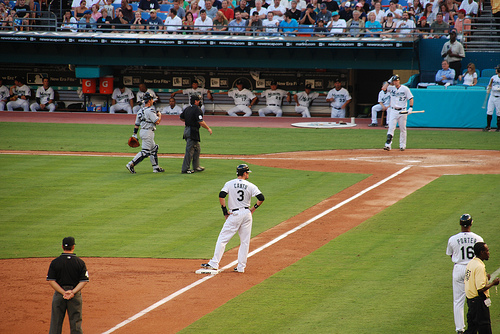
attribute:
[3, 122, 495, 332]
grass — short, green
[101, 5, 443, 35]
people — Watching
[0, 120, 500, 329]
ground — Brown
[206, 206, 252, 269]
trouser — white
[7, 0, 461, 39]
people — watch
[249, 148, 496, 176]
sand — brown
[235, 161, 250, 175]
helmet — black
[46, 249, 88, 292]
t shirt — black